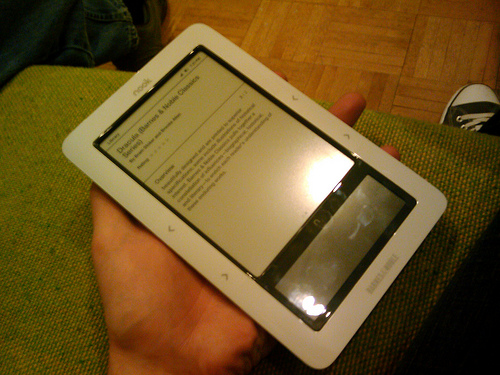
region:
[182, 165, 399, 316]
A tablet in the photo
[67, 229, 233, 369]
A hand in the photo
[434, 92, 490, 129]
A shoe in the photo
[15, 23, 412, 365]
A person holding a tablet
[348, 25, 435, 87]
Wooden floor in the photo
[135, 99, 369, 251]
A screen on the tablet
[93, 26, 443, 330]
A person holding a tablet computer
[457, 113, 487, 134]
Shoe lace in the photo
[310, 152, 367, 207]
Light reflection on the tablet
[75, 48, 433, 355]
a person holding an e reader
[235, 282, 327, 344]
the white border of an ereader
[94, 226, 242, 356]
the palm of a persons hand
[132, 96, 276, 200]
a bunch of text on an ereader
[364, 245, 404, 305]
a logo of a tablet company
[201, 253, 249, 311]
the back button on a tablet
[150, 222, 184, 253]
the home button on a tablet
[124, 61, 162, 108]
a nook logo on a tablet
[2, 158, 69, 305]
a small green throw pillow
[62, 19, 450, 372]
electronic book on hand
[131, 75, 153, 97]
name of company on ebook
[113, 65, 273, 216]
words on device screen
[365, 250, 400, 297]
logo of book store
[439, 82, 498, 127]
black and white sneaker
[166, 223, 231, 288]
arrows on side of device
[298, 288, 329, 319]
glare on device screen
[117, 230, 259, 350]
palm of open hand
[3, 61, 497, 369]
green cushion of couch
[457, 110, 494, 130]
white laces on shoe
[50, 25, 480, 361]
Person holding a nook E-reader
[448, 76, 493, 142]
person wearing black shoes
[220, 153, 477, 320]
Person holding a nook E-reader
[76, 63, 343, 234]
Person holding a nook E-reader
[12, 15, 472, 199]
Person holding a nook E-reader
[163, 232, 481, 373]
Person holding a nook E-reader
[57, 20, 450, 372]
A hand held nook